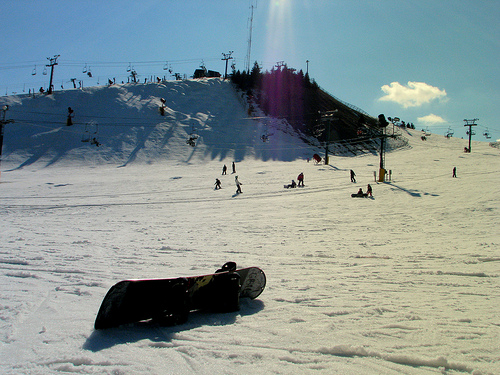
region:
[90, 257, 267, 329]
The snowboard on the ground.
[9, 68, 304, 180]
The snow covered part of the hill in the distance.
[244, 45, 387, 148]
The grass covered part of the hill in the distance.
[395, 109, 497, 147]
The ski lifts on the right in the distance.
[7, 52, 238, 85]
The ski lifts above the snow covered part of the hill.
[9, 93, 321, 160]
The ski lifts in front of the snow covered part of the hill.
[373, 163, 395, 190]
The yellow post of the ski lifts in front of the hill.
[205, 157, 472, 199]
The people near the ski lifts in front of the hill.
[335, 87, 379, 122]
The fence near the grass covered part of the hill.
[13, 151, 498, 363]
The snow area the people are standing.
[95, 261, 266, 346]
a dark overturned snowboard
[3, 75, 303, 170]
a snowy hill side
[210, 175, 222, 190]
a snowboarder going downhill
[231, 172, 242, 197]
a snowboarder going downhill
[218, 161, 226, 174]
a snowboarder going downhill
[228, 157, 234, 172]
a snowboarder going downhill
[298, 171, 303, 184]
a snowboarder going downhill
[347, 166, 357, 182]
a snowboarder going downhill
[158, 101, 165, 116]
a snowboarder going downhill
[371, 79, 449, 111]
a small white cloud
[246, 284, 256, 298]
part of a board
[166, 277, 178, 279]
edge of a board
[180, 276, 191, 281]
tip of a board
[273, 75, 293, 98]
part of a forest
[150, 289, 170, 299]
edge of a board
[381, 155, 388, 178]
edge of a pole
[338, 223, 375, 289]
part of the snow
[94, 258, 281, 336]
THIS IS A SNOWBOARD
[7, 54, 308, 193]
THE PEOPLE ARE ON THE HILL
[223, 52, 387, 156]
THE TREES ARE ON THE HILL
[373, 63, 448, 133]
THIS IS A PUFFY CLOUD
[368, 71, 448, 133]
THE CLOUD IS FLUFFY AND WHITE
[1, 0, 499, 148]
THE CLOUDS ARE IN THE BLUE SKY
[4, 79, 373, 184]
MANY SKIERS ARE ON THE HILL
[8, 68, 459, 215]
MOST OF THE PEOPLE ARE WEARING SKIS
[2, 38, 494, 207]
THE POLES ARE HOLDING UP THE CABLES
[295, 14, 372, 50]
white clouds against blue sky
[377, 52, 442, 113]
white clouds against blue sky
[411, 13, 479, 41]
white clouds against blue sky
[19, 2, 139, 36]
white clouds against blue sky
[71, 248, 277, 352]
snowboard left in snow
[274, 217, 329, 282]
white snow on mountain side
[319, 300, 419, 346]
white snow on mountain side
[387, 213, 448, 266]
white snow on mountain side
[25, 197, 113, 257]
white snow on mountain side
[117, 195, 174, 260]
white snow on mountain side